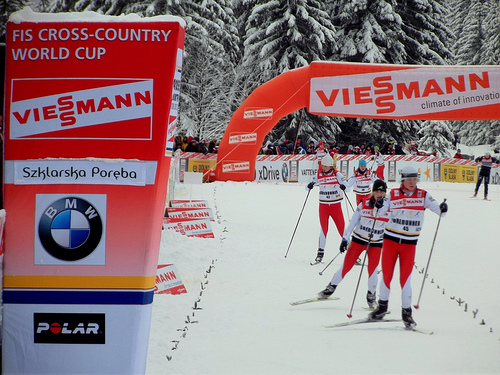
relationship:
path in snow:
[177, 180, 498, 373] [155, 172, 499, 374]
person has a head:
[294, 140, 306, 157] [295, 140, 299, 146]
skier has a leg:
[367, 162, 447, 329] [370, 242, 397, 318]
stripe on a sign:
[2, 290, 154, 305] [0, 10, 186, 374]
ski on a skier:
[324, 316, 401, 324] [367, 162, 447, 329]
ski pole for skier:
[418, 197, 447, 309] [367, 162, 447, 329]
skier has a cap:
[342, 160, 384, 212] [358, 158, 366, 166]